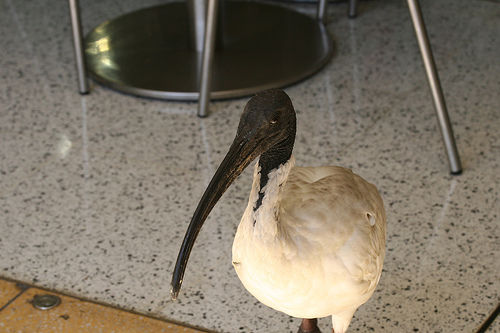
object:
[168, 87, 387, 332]
bird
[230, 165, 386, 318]
body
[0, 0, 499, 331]
floor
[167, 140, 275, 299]
beak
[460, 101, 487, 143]
part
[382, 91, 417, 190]
part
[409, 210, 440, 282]
part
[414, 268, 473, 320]
part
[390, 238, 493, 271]
part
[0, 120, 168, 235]
floor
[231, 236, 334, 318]
chest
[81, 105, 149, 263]
floor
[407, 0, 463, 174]
chair leg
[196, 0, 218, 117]
chair leg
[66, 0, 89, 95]
chair leg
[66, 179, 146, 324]
glass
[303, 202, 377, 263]
feathers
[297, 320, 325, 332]
bird foot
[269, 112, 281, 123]
eye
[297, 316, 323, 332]
leg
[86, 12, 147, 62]
silver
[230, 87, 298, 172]
head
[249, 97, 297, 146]
side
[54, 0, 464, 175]
chair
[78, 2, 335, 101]
base